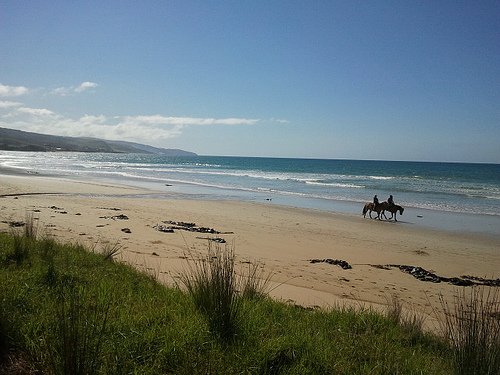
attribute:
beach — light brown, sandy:
[4, 173, 495, 337]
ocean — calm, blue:
[16, 153, 500, 233]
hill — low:
[3, 127, 201, 160]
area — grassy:
[3, 227, 500, 370]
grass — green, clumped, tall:
[174, 233, 296, 345]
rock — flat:
[166, 217, 197, 230]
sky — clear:
[1, 2, 500, 165]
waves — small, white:
[86, 156, 398, 183]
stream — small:
[21, 187, 254, 205]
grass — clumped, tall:
[37, 290, 121, 365]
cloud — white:
[52, 77, 103, 96]